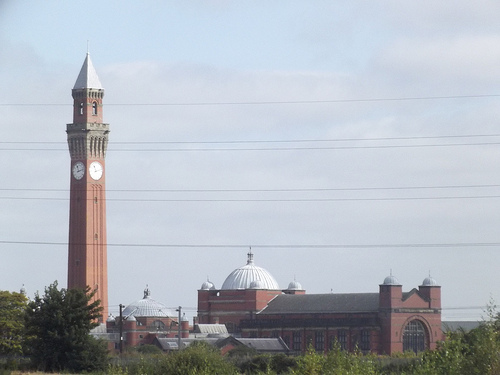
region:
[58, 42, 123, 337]
tall red brick clock tower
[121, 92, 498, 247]
power lines in the sky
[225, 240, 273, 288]
white dome on top of building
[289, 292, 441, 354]
red brick building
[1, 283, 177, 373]
green trees in front of buildings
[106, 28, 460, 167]
blue sky with clouds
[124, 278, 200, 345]
red brick building with white dome top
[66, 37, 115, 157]
pointy top of a tower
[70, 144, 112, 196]
clock on the outside of a redbrick tower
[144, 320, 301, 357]
rooftops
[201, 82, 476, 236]
A series of telephone wires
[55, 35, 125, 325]
A red and grey clocktower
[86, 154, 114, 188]
A round outdoor clock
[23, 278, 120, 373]
a tree with full foliage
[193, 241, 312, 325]
A red building with a dome roof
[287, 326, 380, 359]
windows with black bars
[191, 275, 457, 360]
A red and black building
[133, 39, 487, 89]
cloudy sky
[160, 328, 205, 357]
two sky lights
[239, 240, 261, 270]
decorative roof adornment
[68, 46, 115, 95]
The top of a large tower is pyramid shaped.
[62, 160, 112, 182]
Two clocks on a large tower.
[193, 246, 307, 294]
One large and three small dome shaped roofs.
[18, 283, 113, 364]
A leafy green tree.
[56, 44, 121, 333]
A tall clock tower.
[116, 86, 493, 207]
Several utility lines shown.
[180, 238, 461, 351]
A large brown building.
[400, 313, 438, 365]
Large oval shaped doorway.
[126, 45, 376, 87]
Light fluffy cloud.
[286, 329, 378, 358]
Four windows shown on the side of a brown building.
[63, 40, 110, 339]
tall clock tower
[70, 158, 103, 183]
face of two clocks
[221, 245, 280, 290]
a dome style roof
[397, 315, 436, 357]
an arch shaped window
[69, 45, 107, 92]
a pyramid shaped roof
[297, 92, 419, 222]
telephone wires against the sky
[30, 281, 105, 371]
a green leafy tree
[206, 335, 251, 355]
a gable on a peaked roof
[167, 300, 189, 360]
a telephone pole with wires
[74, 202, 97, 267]
wall made of bricks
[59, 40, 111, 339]
Tan and brown tower next to building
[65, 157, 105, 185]
Two clocks in tower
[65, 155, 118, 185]
Clocks are white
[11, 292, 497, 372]
Vegetation in front of buildings and tower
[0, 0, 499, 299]
Sky is filled with clouds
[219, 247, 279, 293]
White dome on church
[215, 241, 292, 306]
Dome is white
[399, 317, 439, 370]
Big door in in building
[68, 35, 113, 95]
roof of dome is tan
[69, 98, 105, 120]
There are windows in the top of tower